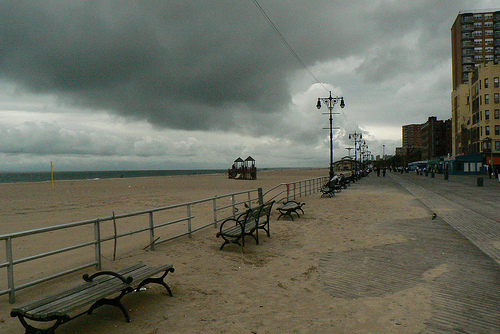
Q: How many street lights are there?
A: Six.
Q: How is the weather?
A: Cloudy.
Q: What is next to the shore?
A: Buildings.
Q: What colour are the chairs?
A: Grey with black stands.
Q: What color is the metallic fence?
A: Grey.